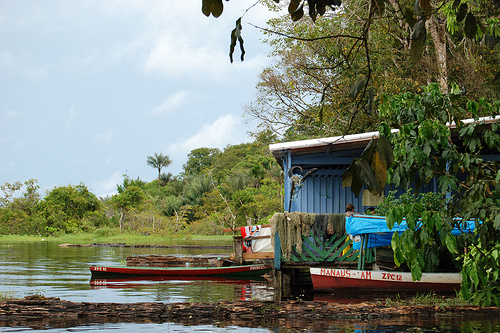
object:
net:
[276, 211, 293, 263]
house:
[265, 114, 494, 276]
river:
[0, 239, 273, 308]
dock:
[123, 219, 275, 270]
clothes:
[344, 210, 414, 253]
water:
[0, 239, 241, 297]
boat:
[86, 263, 272, 286]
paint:
[312, 278, 320, 283]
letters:
[365, 271, 371, 281]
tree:
[350, 70, 498, 311]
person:
[342, 201, 356, 214]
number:
[396, 274, 402, 280]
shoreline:
[116, 243, 235, 250]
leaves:
[272, 87, 277, 90]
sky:
[0, 13, 216, 142]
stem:
[359, 20, 379, 69]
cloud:
[94, 0, 288, 158]